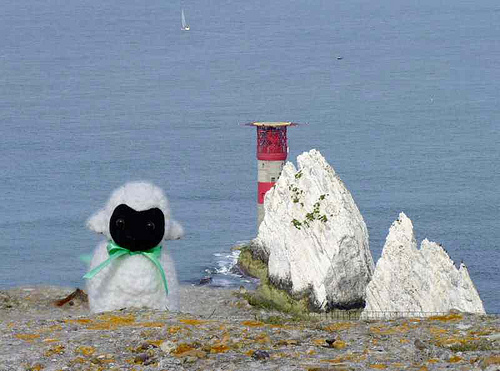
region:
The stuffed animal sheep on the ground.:
[81, 181, 191, 308]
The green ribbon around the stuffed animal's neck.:
[88, 237, 181, 286]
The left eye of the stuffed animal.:
[110, 213, 127, 228]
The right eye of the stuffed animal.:
[144, 217, 159, 238]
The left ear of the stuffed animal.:
[82, 207, 105, 234]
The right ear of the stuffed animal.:
[165, 222, 182, 241]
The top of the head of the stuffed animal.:
[106, 183, 166, 207]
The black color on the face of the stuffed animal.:
[111, 202, 165, 249]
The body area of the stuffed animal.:
[88, 247, 178, 309]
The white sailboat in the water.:
[172, 8, 197, 35]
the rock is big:
[240, 140, 402, 338]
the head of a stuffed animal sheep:
[81, 179, 190, 256]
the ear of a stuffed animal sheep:
[161, 215, 191, 246]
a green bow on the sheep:
[77, 240, 177, 300]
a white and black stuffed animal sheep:
[68, 175, 193, 325]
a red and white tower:
[241, 110, 293, 235]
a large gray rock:
[351, 197, 490, 323]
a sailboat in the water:
[173, 3, 194, 35]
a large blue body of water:
[0, 0, 499, 322]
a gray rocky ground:
[1, 285, 499, 369]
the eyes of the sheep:
[114, 212, 156, 231]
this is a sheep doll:
[74, 177, 186, 311]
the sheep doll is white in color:
[76, 180, 191, 316]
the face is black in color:
[124, 213, 157, 240]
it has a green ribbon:
[109, 244, 161, 265]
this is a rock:
[257, 177, 351, 289]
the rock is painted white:
[274, 190, 346, 277]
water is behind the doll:
[47, 53, 232, 159]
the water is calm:
[67, 51, 215, 129]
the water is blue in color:
[60, 37, 223, 147]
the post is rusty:
[250, 122, 288, 162]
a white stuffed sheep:
[78, 174, 190, 316]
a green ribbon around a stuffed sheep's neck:
[86, 239, 182, 296]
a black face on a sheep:
[106, 202, 167, 258]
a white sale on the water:
[177, 6, 197, 36]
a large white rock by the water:
[257, 151, 373, 303]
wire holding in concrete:
[206, 305, 497, 331]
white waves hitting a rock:
[215, 236, 243, 283]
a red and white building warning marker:
[246, 112, 306, 228]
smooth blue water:
[3, 3, 498, 303]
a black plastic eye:
[114, 213, 125, 228]